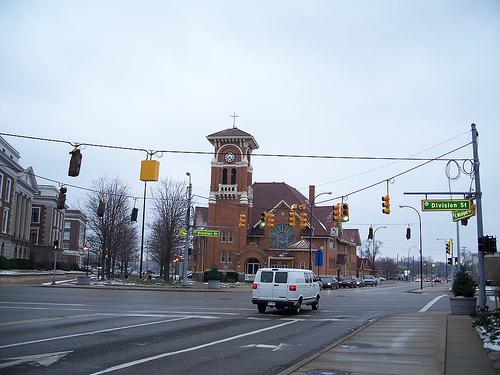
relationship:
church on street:
[192, 105, 361, 282] [1, 256, 458, 369]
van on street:
[247, 263, 327, 317] [3, 263, 495, 373]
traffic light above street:
[382, 195, 390, 212] [3, 263, 495, 373]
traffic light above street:
[333, 202, 349, 222] [3, 263, 495, 373]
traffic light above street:
[332, 203, 341, 221] [3, 263, 495, 373]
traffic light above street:
[298, 212, 306, 230] [3, 263, 495, 373]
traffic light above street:
[288, 210, 297, 227] [3, 263, 495, 373]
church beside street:
[187, 105, 363, 285] [6, 279, 493, 372]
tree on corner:
[453, 267, 473, 297] [383, 287, 491, 334]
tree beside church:
[144, 176, 193, 282] [182, 109, 380, 285]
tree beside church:
[83, 172, 133, 273] [182, 109, 380, 285]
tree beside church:
[71, 175, 139, 280] [182, 109, 380, 285]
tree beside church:
[143, 219, 188, 276] [182, 109, 380, 285]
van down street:
[252, 268, 321, 315] [3, 263, 495, 373]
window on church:
[268, 220, 298, 248] [182, 109, 380, 285]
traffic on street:
[326, 273, 387, 288] [3, 270, 453, 374]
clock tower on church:
[206, 128, 251, 279] [187, 105, 363, 285]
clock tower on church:
[205, 112, 260, 279] [187, 105, 363, 285]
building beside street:
[0, 136, 88, 272] [3, 270, 453, 374]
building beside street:
[28, 185, 69, 270] [3, 270, 453, 374]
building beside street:
[185, 108, 366, 278] [3, 270, 453, 374]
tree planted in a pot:
[452, 265, 478, 297] [447, 296, 479, 313]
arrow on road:
[238, 341, 301, 351] [1, 281, 436, 373]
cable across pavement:
[0, 120, 491, 206] [0, 274, 500, 374]